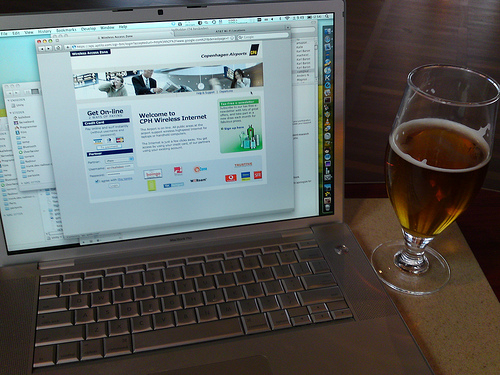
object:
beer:
[388, 117, 484, 231]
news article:
[136, 110, 211, 154]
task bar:
[322, 25, 331, 208]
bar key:
[131, 317, 244, 352]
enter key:
[300, 271, 337, 290]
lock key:
[35, 310, 75, 331]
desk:
[4, 197, 499, 371]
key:
[277, 291, 302, 310]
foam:
[388, 117, 493, 173]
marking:
[385, 160, 394, 167]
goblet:
[368, 64, 498, 298]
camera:
[157, 9, 163, 16]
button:
[333, 244, 349, 258]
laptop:
[0, 0, 436, 371]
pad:
[167, 353, 281, 373]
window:
[0, 23, 334, 255]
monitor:
[1, 14, 338, 250]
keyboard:
[11, 239, 353, 364]